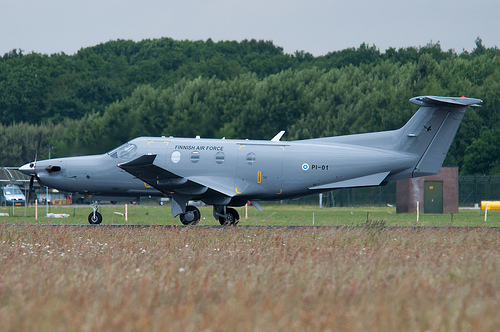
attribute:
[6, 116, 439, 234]
airplane — finnish, parked, pi01, grey, silver, long, p101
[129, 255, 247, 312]
field — grassy, dry, brown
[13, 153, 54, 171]
propeller — still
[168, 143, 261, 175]
windows — cockpit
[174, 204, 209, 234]
wheel — black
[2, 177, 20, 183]
building — brick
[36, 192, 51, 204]
door — green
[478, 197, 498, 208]
barrel — yellow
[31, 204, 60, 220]
flowers — white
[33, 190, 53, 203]
car — parked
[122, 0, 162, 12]
sky — overast, blue